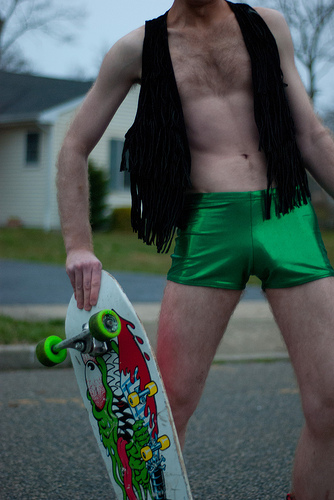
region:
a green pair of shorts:
[158, 190, 332, 286]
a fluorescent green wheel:
[37, 329, 64, 369]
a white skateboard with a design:
[56, 276, 203, 498]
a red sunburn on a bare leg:
[154, 311, 183, 375]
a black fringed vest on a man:
[117, 8, 298, 222]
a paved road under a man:
[9, 363, 332, 498]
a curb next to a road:
[3, 343, 80, 368]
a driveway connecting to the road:
[1, 256, 332, 349]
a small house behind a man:
[7, 65, 199, 228]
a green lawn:
[9, 225, 181, 266]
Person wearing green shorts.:
[178, 191, 248, 266]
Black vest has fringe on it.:
[112, 64, 226, 183]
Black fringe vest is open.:
[116, 117, 324, 192]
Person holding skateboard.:
[42, 258, 163, 379]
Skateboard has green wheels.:
[92, 322, 122, 354]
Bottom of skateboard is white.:
[92, 372, 158, 491]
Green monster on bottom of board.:
[86, 352, 156, 492]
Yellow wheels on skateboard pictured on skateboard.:
[122, 377, 176, 491]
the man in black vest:
[70, 13, 307, 196]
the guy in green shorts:
[106, 137, 327, 327]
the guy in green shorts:
[73, 12, 330, 275]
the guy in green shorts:
[43, 53, 239, 274]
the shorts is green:
[154, 214, 332, 321]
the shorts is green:
[143, 130, 310, 348]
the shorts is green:
[146, 180, 232, 229]